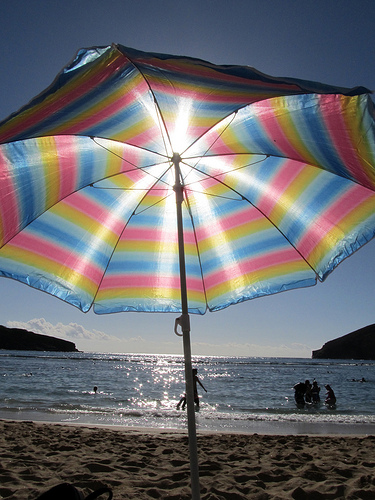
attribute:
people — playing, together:
[323, 385, 337, 417]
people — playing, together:
[311, 381, 324, 409]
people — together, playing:
[302, 377, 313, 402]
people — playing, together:
[294, 381, 306, 416]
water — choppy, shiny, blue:
[0, 358, 372, 430]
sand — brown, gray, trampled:
[0, 423, 372, 499]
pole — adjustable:
[173, 158, 198, 500]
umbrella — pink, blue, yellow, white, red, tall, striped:
[4, 43, 375, 500]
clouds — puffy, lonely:
[14, 319, 157, 352]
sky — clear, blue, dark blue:
[0, 0, 371, 358]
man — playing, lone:
[187, 364, 206, 411]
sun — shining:
[79, 90, 329, 300]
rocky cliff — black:
[297, 475, 362, 499]